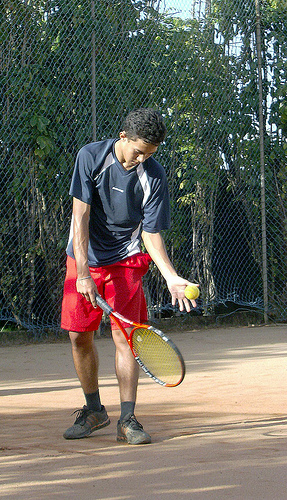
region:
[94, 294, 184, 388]
black and orange tennis racquet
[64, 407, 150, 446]
black and orange sneakers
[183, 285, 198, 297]
yellow tennis ball in hand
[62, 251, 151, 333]
red cotton tennis shorts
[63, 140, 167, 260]
blue and grey tee shirt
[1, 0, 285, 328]
grey metal chain link fence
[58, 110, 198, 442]
man playing tennis match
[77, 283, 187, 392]
tennis racquet in hand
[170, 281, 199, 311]
tennis ball in hand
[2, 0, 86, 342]
tree with green leaves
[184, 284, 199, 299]
Yellow tennis ball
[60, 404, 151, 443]
Black and orange pair of tennis shoes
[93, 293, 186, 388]
Black and orange tennis racket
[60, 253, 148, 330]
Red pair of shorts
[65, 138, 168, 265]
Black and white t shirt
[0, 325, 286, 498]
Tan tennis court ground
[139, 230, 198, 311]
Man's arm holding a tennis ball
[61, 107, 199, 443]
Man preparing to serve a tennis ball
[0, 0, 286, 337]
Chain link fence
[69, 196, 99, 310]
Man's arm holding a tennis racket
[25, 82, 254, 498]
a boy playing tennis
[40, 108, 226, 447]
a boy holding a racket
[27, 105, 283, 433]
a boy holding a tennis racket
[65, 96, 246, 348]
a boy holding a yellow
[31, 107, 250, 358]
a man holding a tennis ball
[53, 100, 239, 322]
a man holding a yellow tennis ball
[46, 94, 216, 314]
a man with black hair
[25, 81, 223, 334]
a man in shirt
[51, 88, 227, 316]
a man wearing a black shirt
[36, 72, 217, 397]
a man wearing shorts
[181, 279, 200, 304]
A small yellow tennis ball.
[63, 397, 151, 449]
A mans' tennis shoes and gray socks.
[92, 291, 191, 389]
A tennis racket in mid swing.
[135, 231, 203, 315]
A hand throwing a tennis ball.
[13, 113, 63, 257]
A tree behind a fence.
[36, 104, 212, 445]
A man playing tennis.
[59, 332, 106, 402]
A mans' hairy leg.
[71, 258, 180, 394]
A man holding a tennis racket.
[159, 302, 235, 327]
A broken metal fence.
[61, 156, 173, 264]
A gray and white tee shirt.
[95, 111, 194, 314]
tennis player holding a ball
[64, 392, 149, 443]
tennis player's black shoes and black socks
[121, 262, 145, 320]
red shorts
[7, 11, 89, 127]
trees behind a chain link fence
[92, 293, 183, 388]
tennis racket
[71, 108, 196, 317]
man looking down toward a tennis ball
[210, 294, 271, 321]
opening in the bottom of the chain link fence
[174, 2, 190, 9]
blue sky behind the fence and trees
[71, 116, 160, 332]
man wearing a blue shirt and red shorts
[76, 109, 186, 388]
man holding a tennis racket